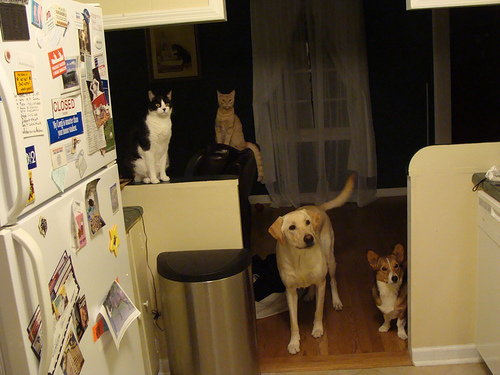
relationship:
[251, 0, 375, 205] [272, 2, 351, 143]
curtains are on window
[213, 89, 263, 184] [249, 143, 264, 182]
cat has tail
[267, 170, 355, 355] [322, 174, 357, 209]
dog has tail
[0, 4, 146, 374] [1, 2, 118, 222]
refrigerator has door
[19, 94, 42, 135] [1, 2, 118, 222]
post on door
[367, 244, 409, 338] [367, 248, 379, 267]
dog has ear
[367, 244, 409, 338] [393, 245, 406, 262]
dog has ear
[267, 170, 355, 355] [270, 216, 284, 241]
dog has ear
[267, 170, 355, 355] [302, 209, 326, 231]
dog has ear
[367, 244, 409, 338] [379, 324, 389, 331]
dog has paw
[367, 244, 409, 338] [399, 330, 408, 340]
dog has paw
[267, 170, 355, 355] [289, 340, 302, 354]
dog has paw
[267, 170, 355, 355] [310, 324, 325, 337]
dog has paw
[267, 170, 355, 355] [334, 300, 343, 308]
dog has paw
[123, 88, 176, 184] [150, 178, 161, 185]
cat has paw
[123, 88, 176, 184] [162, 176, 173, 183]
cat has paw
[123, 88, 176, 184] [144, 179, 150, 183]
cat has paw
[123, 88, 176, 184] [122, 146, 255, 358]
cat sitting on counter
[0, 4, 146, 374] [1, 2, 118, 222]
fridge has door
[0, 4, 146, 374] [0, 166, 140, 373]
fridge has door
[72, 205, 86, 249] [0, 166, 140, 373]
object tacked to door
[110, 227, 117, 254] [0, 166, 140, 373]
object tacked to door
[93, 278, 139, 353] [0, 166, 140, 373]
object tacked to door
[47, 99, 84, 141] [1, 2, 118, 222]
object tacked to door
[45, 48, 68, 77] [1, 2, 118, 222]
object tacked to door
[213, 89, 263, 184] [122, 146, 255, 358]
cat on top of table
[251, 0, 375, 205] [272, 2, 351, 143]
curtain hangs over window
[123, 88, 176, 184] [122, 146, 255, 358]
cat on top of table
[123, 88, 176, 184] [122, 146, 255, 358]
cat on top of shelf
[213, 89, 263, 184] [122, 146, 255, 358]
cat on top of shelf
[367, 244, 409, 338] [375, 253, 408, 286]
dog has head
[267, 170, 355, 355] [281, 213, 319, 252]
dog has head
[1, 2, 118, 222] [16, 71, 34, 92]
door has magnet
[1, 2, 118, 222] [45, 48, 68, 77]
door has magnet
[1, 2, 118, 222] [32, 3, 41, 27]
door has magnet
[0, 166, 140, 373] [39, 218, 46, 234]
door has magnet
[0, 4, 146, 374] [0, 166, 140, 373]
refrigerator has door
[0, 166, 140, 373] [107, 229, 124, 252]
door has magnet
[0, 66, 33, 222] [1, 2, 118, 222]
handle connected to door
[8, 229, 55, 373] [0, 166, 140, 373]
handle connected to door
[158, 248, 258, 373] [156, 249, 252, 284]
trash can has lid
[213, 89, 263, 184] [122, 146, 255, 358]
cat sitting on counter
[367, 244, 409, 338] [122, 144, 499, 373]
dog looking into kitchen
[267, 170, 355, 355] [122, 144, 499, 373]
dog looking into kitchen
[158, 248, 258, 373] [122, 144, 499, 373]
trash can inside of kitchen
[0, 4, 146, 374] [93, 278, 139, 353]
refrigerator has paper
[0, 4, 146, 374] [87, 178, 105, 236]
refrigerator has paper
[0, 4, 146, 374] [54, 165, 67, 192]
refrigerator has paper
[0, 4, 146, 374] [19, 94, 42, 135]
refrigerator has paper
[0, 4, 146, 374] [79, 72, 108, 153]
refrigerator has paper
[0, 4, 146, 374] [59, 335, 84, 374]
refrigerator has paper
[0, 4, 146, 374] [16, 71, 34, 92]
refrigerator has magnet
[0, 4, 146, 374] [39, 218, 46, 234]
refrigerator has magnet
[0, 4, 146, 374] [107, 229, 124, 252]
refrigerator has magnet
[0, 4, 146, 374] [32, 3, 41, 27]
refrigerator has magnet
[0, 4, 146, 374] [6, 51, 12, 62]
refrigerator has magnet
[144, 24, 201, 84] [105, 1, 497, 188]
picture hanging on wall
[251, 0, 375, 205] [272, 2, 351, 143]
curtains hanging at window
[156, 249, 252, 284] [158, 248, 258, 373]
top on top of trash can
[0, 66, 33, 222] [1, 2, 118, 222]
handle connected to freezer